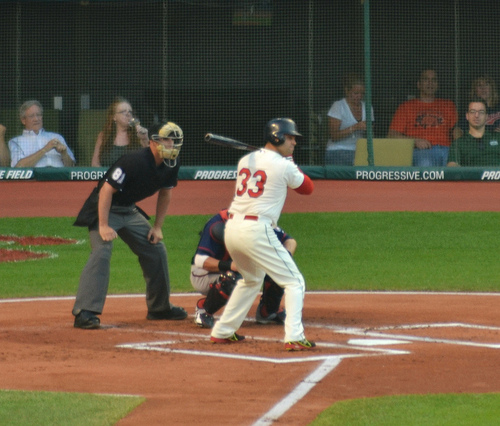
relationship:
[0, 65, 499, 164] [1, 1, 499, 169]
fans sitting behind fence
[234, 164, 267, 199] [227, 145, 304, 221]
33 on back of shirt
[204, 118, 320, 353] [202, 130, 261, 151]
batter holding bat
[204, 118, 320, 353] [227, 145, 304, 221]
batter wearing shirt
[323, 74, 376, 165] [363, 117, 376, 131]
woman texting on cellphone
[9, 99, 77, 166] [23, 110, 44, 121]
man wearing glasses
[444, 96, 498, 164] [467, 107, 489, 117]
man wearing glasses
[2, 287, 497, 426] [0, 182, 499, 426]
stripes on top of field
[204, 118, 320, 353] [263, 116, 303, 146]
batter wearing helmet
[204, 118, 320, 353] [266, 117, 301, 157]
batter has head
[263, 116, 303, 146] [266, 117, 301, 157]
helmet on top of head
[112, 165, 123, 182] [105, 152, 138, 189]
8 on side of sleeve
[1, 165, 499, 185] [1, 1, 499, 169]
progressive banner on bottom of fence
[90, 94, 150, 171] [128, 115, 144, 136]
woman drinking wine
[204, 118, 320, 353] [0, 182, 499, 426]
batter on top of field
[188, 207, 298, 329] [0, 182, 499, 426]
catcher on top of field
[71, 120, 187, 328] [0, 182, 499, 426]
umpire on top of field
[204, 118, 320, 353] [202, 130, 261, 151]
batter about to swing bat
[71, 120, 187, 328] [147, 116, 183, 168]
umpire wearing helmet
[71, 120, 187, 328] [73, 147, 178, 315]
umpire wearing clothing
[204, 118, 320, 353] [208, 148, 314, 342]
batter wearing uniform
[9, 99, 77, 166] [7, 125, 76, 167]
man wearing shirt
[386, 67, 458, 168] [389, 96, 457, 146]
man wearing t-shirt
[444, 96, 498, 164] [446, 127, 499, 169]
man wearing shirt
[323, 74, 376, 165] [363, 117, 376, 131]
woman looking at cellphone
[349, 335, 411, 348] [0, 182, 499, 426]
home plate on top of field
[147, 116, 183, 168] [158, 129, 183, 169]
helmet has face guard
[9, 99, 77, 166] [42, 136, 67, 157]
man has hands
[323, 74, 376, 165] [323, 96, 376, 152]
woman wearing shirt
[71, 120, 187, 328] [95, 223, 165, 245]
umpire has hands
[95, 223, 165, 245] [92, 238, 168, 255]
hands resting on knees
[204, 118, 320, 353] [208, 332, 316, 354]
batter wearing cleats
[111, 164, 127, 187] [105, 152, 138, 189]
81 printed o sleeve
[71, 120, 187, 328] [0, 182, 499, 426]
umpire o top of field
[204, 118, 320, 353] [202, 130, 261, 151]
batter swinging bat